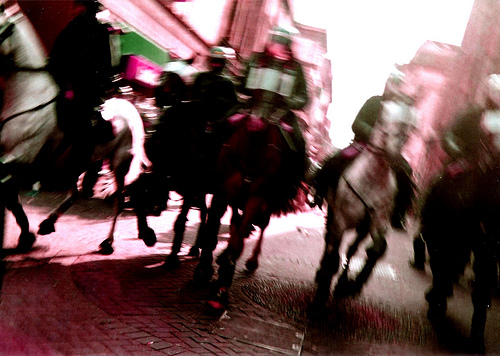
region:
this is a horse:
[314, 84, 429, 321]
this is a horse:
[423, 133, 493, 338]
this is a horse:
[131, 45, 244, 256]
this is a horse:
[153, 95, 259, 316]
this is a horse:
[5, 7, 165, 280]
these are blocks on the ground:
[96, 305, 146, 345]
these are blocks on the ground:
[168, 320, 198, 346]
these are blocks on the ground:
[236, 310, 246, 328]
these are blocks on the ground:
[124, 319, 164, 349]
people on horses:
[0, 1, 480, 332]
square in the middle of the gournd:
[210, 305, 305, 350]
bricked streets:
[0, 195, 490, 351]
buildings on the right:
[370, 0, 497, 243]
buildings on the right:
[5, 0, 335, 211]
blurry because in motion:
[2, 0, 492, 345]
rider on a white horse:
[1, 1, 151, 243]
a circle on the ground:
[73, 226, 389, 352]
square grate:
[325, 245, 405, 283]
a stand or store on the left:
[105, 15, 169, 211]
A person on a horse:
[309, 37, 451, 326]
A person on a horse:
[238, 11, 312, 233]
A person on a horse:
[146, 15, 244, 204]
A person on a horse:
[3, 0, 155, 277]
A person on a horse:
[431, 52, 496, 264]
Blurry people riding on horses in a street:
[5, 5, 499, 345]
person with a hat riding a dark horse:
[186, 20, 310, 323]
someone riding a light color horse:
[303, 59, 417, 330]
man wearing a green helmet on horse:
[141, 43, 243, 286]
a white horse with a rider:
[2, 0, 151, 263]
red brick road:
[6, 164, 496, 354]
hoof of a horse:
[34, 207, 59, 247]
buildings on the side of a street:
[377, 2, 498, 218]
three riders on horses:
[147, 16, 424, 343]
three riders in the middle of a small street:
[142, 24, 421, 322]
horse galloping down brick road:
[7, 19, 93, 245]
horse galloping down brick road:
[141, 54, 216, 244]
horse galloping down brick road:
[220, 70, 280, 275]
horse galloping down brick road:
[317, 88, 415, 305]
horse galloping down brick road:
[410, 125, 497, 337]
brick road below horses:
[2, 192, 449, 347]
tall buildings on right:
[376, 28, 498, 223]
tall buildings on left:
[2, 33, 344, 175]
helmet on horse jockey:
[259, 19, 301, 52]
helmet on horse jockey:
[370, 73, 409, 90]